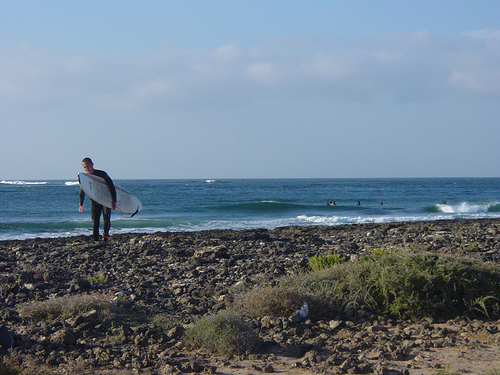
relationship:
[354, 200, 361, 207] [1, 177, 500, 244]
person swimming in ocean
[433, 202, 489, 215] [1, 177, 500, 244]
wave in ocean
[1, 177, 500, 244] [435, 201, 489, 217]
ocean has white spray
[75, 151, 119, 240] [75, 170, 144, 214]
man carrying surfboard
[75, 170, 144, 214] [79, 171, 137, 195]
surfboard has strip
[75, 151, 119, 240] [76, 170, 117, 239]
man in wetsuit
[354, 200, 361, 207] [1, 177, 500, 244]
person in ocean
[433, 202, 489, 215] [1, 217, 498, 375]
wave breaking against ground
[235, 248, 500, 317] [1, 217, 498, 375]
vegetation on ground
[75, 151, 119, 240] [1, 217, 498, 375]
man walking on ground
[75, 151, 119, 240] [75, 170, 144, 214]
man leaving with surfboard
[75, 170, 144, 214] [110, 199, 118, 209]
surfboard in hand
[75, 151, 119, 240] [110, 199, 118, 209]
man has hand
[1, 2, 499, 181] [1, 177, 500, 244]
sky above ocean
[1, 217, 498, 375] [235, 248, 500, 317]
ground has vegetation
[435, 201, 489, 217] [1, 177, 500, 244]
white spray in ocean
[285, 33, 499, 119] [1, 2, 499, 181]
cloud in sky